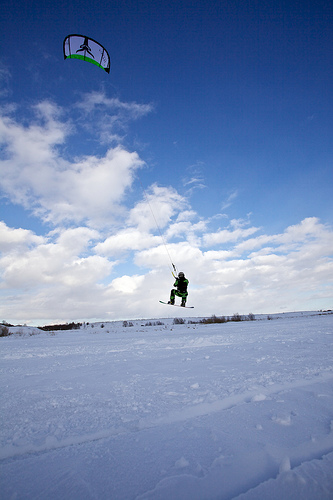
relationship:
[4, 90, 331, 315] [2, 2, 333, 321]
clouds are in sky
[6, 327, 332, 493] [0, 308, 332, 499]
snow on ground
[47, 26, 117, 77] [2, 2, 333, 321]
kite in sky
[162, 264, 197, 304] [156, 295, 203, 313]
man on snowboard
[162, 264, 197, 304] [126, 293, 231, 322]
man in air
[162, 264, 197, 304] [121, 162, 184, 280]
man holding kite string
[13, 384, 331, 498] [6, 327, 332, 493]
markings are in snow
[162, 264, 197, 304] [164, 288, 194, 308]
man wearing pants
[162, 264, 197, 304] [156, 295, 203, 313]
man on a snowboard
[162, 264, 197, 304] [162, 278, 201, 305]
man wearing clothes